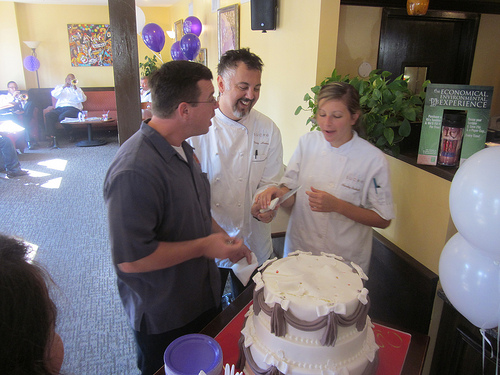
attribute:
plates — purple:
[156, 331, 222, 370]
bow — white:
[250, 272, 267, 294]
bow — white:
[264, 288, 295, 313]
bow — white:
[315, 295, 350, 319]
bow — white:
[352, 287, 371, 307]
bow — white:
[351, 257, 368, 281]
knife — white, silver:
[238, 181, 303, 222]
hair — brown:
[315, 79, 357, 117]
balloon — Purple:
[141, 22, 165, 53]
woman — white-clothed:
[254, 80, 396, 307]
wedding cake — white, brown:
[228, 239, 385, 374]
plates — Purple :
[163, 332, 224, 373]